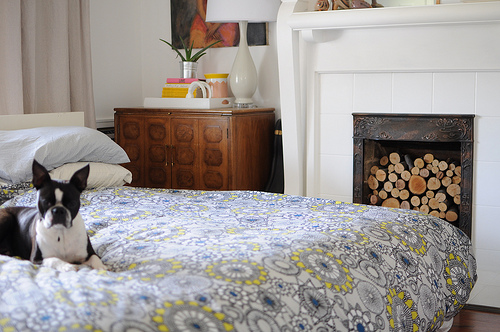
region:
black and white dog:
[0, 157, 107, 272]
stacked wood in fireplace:
[368, 151, 458, 210]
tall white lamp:
[201, 0, 277, 105]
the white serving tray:
[137, 93, 237, 110]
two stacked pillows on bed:
[0, 124, 132, 190]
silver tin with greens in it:
[158, 34, 210, 80]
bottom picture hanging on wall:
[167, 1, 272, 51]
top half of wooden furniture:
[108, 102, 280, 188]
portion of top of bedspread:
[140, 200, 307, 268]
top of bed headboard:
[0, 110, 92, 130]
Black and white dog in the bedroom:
[0, 0, 499, 330]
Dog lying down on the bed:
[2, 112, 477, 329]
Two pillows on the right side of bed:
[1, 124, 133, 189]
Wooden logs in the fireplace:
[357, 137, 462, 222]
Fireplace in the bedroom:
[350, 110, 475, 239]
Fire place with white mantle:
[274, 2, 499, 308]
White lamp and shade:
[201, 0, 286, 105]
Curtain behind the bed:
[0, 1, 98, 128]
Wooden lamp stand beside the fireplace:
[112, 105, 277, 190]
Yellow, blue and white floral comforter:
[1, 184, 478, 330]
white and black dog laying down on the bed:
[6, 162, 136, 283]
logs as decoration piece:
[359, 127, 464, 224]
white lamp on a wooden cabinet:
[205, 0, 282, 113]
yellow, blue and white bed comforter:
[2, 182, 476, 324]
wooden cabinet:
[112, 100, 267, 194]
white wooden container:
[139, 82, 240, 114]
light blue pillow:
[0, 124, 133, 165]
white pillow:
[43, 158, 137, 194]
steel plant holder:
[177, 57, 200, 78]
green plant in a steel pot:
[160, 33, 217, 70]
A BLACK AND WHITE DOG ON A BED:
[1, 159, 146, 282]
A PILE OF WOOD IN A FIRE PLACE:
[354, 142, 476, 229]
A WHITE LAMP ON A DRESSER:
[201, 0, 281, 106]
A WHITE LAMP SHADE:
[201, 0, 291, 30]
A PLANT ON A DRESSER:
[158, 31, 219, 78]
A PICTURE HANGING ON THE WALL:
[156, 2, 248, 56]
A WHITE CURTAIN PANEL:
[3, 5, 99, 117]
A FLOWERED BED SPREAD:
[86, 188, 479, 325]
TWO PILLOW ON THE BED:
[4, 123, 139, 190]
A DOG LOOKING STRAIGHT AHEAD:
[8, 154, 107, 274]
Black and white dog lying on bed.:
[1, 144, 112, 285]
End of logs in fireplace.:
[365, 146, 461, 223]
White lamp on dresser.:
[203, 4, 282, 121]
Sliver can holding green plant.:
[160, 32, 224, 84]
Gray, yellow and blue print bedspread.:
[159, 187, 447, 330]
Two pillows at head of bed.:
[7, 119, 144, 193]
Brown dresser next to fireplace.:
[112, 102, 277, 207]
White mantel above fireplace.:
[289, 4, 495, 33]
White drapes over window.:
[4, 3, 109, 136]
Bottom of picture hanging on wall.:
[162, 8, 277, 53]